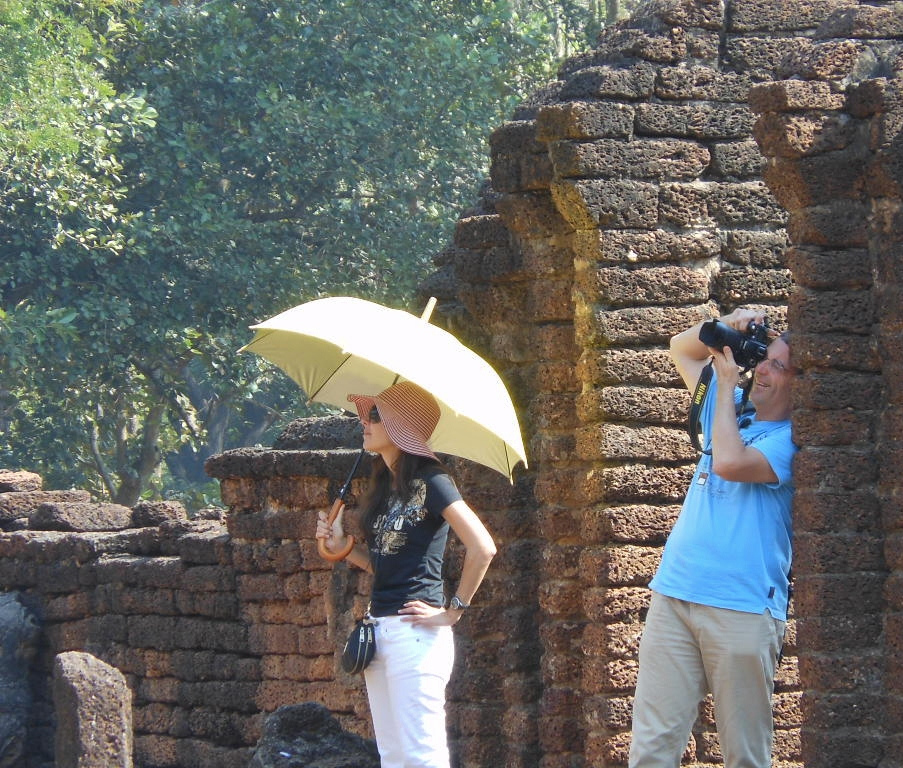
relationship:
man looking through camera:
[629, 302, 792, 765] [697, 318, 767, 376]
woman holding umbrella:
[314, 378, 498, 766] [244, 292, 532, 488]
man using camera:
[629, 302, 792, 765] [697, 318, 767, 376]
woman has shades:
[314, 378, 498, 766] [367, 401, 380, 422]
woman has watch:
[314, 378, 498, 766] [449, 592, 466, 613]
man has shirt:
[629, 302, 792, 765] [651, 368, 794, 619]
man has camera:
[629, 302, 792, 765] [697, 318, 767, 376]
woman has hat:
[314, 378, 498, 766] [350, 383, 438, 459]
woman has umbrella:
[314, 378, 498, 766] [244, 292, 532, 488]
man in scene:
[629, 302, 792, 765] [2, 4, 900, 765]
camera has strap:
[697, 318, 767, 376] [682, 358, 754, 456]